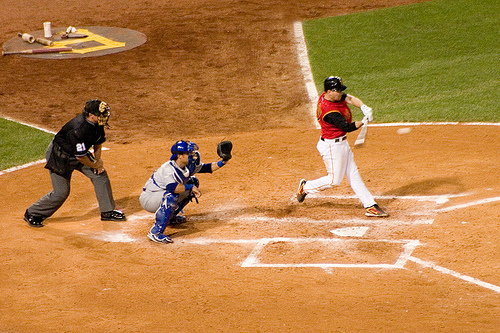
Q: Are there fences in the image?
A: No, there are no fences.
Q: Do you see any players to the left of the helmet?
A: No, the player is to the right of the helmet.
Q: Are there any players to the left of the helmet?
A: No, the player is to the right of the helmet.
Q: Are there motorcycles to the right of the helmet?
A: No, there is a player to the right of the helmet.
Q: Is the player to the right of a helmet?
A: Yes, the player is to the right of a helmet.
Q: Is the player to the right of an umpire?
A: No, the player is to the right of a helmet.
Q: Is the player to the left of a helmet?
A: No, the player is to the right of a helmet.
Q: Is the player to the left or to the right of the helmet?
A: The player is to the right of the helmet.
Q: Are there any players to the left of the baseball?
A: Yes, there is a player to the left of the baseball.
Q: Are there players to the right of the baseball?
A: No, the player is to the left of the baseball.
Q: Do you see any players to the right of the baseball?
A: No, the player is to the left of the baseball.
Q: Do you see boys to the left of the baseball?
A: No, there is a player to the left of the baseball.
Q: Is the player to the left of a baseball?
A: Yes, the player is to the left of a baseball.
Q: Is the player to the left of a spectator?
A: No, the player is to the left of a baseball.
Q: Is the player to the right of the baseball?
A: No, the player is to the left of the baseball.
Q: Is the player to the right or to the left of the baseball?
A: The player is to the left of the baseball.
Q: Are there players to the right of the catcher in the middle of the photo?
A: Yes, there is a player to the right of the catcher.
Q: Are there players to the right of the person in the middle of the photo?
A: Yes, there is a player to the right of the catcher.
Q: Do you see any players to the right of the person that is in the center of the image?
A: Yes, there is a player to the right of the catcher.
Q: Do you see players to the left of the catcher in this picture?
A: No, the player is to the right of the catcher.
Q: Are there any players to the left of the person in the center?
A: No, the player is to the right of the catcher.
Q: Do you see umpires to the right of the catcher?
A: No, there is a player to the right of the catcher.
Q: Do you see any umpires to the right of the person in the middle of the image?
A: No, there is a player to the right of the catcher.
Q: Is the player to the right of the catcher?
A: Yes, the player is to the right of the catcher.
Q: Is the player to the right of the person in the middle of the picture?
A: Yes, the player is to the right of the catcher.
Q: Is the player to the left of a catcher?
A: No, the player is to the right of a catcher.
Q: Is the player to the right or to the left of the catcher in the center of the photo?
A: The player is to the right of the catcher.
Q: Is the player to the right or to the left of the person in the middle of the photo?
A: The player is to the right of the catcher.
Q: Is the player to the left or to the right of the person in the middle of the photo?
A: The player is to the right of the catcher.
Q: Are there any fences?
A: No, there are no fences.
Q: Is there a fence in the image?
A: No, there are no fences.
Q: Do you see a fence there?
A: No, there are no fences.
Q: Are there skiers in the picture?
A: No, there are no skiers.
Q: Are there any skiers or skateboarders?
A: No, there are no skiers or skateboarders.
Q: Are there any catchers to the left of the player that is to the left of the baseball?
A: Yes, there is a catcher to the left of the player.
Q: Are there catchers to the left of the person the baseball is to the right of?
A: Yes, there is a catcher to the left of the player.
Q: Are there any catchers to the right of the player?
A: No, the catcher is to the left of the player.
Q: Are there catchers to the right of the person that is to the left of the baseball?
A: No, the catcher is to the left of the player.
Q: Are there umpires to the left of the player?
A: No, there is a catcher to the left of the player.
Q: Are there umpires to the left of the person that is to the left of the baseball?
A: No, there is a catcher to the left of the player.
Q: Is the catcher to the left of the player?
A: Yes, the catcher is to the left of the player.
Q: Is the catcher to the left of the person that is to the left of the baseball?
A: Yes, the catcher is to the left of the player.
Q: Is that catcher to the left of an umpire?
A: No, the catcher is to the left of the player.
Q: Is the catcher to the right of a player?
A: No, the catcher is to the left of a player.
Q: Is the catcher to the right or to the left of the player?
A: The catcher is to the left of the player.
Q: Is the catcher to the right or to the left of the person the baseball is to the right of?
A: The catcher is to the left of the player.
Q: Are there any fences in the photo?
A: No, there are no fences.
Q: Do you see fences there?
A: No, there are no fences.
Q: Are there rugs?
A: No, there are no rugs.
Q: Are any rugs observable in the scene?
A: No, there are no rugs.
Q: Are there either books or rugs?
A: No, there are no rugs or books.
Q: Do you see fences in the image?
A: No, there are no fences.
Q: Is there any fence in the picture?
A: No, there are no fences.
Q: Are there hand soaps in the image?
A: No, there are no hand soaps.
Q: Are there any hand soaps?
A: No, there are no hand soaps.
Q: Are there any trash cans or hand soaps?
A: No, there are no hand soaps or trash cans.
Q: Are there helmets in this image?
A: Yes, there is a helmet.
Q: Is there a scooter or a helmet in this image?
A: Yes, there is a helmet.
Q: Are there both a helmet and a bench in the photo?
A: No, there is a helmet but no benches.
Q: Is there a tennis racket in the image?
A: No, there are no rackets.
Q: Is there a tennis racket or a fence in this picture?
A: No, there are no rackets or fences.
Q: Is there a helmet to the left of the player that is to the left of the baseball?
A: Yes, there is a helmet to the left of the player.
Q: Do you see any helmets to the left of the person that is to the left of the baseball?
A: Yes, there is a helmet to the left of the player.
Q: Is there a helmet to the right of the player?
A: No, the helmet is to the left of the player.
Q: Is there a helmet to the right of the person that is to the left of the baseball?
A: No, the helmet is to the left of the player.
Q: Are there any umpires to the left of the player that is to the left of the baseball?
A: No, there is a helmet to the left of the player.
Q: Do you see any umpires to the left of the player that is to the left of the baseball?
A: No, there is a helmet to the left of the player.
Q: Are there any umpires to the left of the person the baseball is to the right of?
A: No, there is a helmet to the left of the player.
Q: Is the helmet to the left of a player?
A: Yes, the helmet is to the left of a player.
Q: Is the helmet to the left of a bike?
A: No, the helmet is to the left of a player.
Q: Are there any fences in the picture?
A: No, there are no fences.